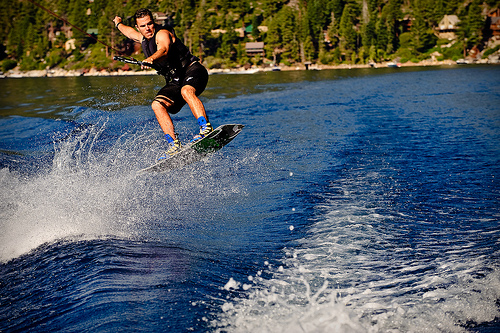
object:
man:
[94, 11, 269, 163]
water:
[0, 70, 499, 332]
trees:
[0, 4, 42, 64]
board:
[129, 127, 245, 178]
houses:
[176, 7, 293, 61]